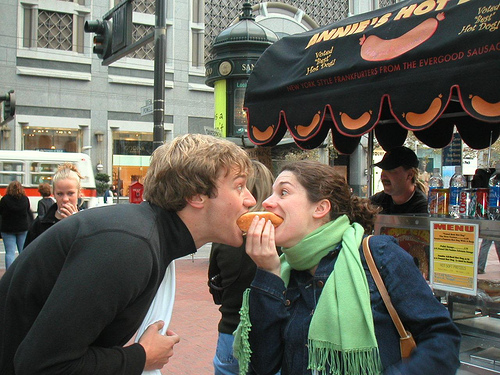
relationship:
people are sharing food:
[1, 134, 462, 374] [237, 212, 284, 233]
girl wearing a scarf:
[245, 158, 460, 374] [231, 214, 382, 373]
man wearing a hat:
[369, 147, 428, 213] [368, 144, 418, 169]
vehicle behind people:
[1, 150, 98, 220] [1, 134, 462, 374]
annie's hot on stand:
[305, 0, 447, 46] [244, 0, 500, 374]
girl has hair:
[245, 158, 460, 374] [279, 160, 384, 234]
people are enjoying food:
[1, 134, 462, 374] [237, 212, 284, 233]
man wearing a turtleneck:
[1, 133, 255, 373] [1, 200, 198, 374]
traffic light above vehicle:
[83, 18, 105, 55] [1, 150, 98, 220]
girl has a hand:
[245, 158, 460, 374] [245, 214, 281, 270]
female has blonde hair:
[22, 162, 95, 250] [50, 163, 85, 196]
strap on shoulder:
[362, 233, 409, 339] [358, 229, 404, 278]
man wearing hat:
[369, 147, 428, 213] [368, 144, 418, 169]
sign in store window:
[112, 140, 153, 157] [113, 130, 166, 198]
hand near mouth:
[245, 214, 281, 270] [271, 214, 284, 230]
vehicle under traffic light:
[1, 150, 98, 220] [83, 18, 105, 55]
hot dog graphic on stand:
[359, 11, 445, 61] [244, 0, 500, 374]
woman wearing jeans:
[1, 180, 32, 270] [0, 232, 27, 272]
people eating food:
[1, 134, 462, 374] [237, 212, 284, 233]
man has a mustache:
[369, 147, 428, 213] [380, 178, 391, 184]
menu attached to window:
[429, 221, 479, 297] [382, 228, 500, 343]